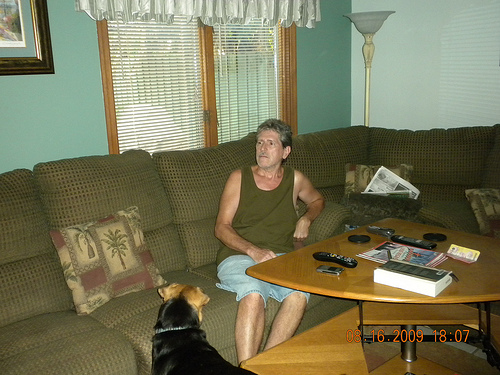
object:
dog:
[150, 273, 244, 371]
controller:
[312, 251, 357, 268]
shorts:
[217, 253, 310, 303]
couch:
[0, 118, 499, 375]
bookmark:
[449, 273, 459, 283]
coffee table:
[244, 217, 500, 374]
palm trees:
[57, 210, 162, 310]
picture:
[0, 0, 51, 76]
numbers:
[344, 324, 476, 347]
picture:
[0, 0, 500, 374]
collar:
[155, 323, 193, 334]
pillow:
[52, 202, 167, 321]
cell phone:
[316, 265, 345, 278]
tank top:
[214, 165, 296, 266]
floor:
[421, 315, 500, 374]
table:
[248, 213, 498, 321]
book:
[370, 258, 458, 297]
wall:
[1, 6, 499, 173]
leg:
[235, 291, 267, 367]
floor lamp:
[345, 9, 395, 123]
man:
[215, 116, 313, 363]